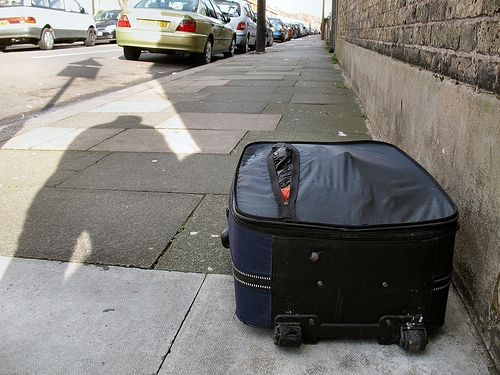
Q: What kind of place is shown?
A: It is a sidewalk.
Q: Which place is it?
A: It is a sidewalk.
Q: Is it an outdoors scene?
A: Yes, it is outdoors.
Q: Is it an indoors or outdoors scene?
A: It is outdoors.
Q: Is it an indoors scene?
A: No, it is outdoors.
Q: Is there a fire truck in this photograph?
A: No, there are no fire trucks.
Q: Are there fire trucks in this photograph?
A: No, there are no fire trucks.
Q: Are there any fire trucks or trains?
A: No, there are no fire trucks or trains.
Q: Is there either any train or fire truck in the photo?
A: No, there are no fire trucks or trains.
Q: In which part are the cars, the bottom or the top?
A: The cars are in the top of the image.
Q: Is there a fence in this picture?
A: No, there are no fences.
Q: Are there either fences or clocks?
A: No, there are no fences or clocks.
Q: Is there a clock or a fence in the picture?
A: No, there are no fences or clocks.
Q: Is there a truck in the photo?
A: No, there are no trucks.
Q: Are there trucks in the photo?
A: No, there are no trucks.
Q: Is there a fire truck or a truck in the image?
A: No, there are no trucks or fire trucks.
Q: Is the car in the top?
A: Yes, the car is in the top of the image.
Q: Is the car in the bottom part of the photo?
A: No, the car is in the top of the image.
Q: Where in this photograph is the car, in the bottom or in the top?
A: The car is in the top of the image.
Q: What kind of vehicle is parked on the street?
A: The vehicle is a car.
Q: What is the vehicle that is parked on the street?
A: The vehicle is a car.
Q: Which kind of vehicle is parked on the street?
A: The vehicle is a car.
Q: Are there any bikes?
A: No, there are no bikes.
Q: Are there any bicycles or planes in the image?
A: No, there are no bicycles or planes.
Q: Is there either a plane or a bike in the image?
A: No, there are no bikes or airplanes.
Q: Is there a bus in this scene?
A: No, there are no buses.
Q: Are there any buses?
A: No, there are no buses.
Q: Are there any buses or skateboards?
A: No, there are no buses or skateboards.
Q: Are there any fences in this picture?
A: No, there are no fences.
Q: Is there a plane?
A: No, there are no airplanes.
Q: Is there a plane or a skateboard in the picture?
A: No, there are no airplanes or skateboards.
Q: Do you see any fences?
A: No, there are no fences.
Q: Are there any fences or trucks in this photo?
A: No, there are no fences or trucks.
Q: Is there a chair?
A: No, there are no chairs.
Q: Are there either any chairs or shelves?
A: No, there are no chairs or shelves.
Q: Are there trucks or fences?
A: No, there are no trucks or fences.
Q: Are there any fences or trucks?
A: No, there are no trucks or fences.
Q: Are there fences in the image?
A: No, there are no fences.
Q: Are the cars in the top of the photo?
A: Yes, the cars are in the top of the image.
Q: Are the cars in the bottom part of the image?
A: No, the cars are in the top of the image.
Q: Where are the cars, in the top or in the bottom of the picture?
A: The cars are in the top of the image.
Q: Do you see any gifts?
A: No, there are no gifts.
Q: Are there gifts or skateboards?
A: No, there are no gifts or skateboards.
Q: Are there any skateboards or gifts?
A: No, there are no gifts or skateboards.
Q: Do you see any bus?
A: No, there are no buses.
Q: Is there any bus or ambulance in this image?
A: No, there are no buses or ambulances.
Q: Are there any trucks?
A: No, there are no trucks.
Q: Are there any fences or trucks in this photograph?
A: No, there are no trucks or fences.